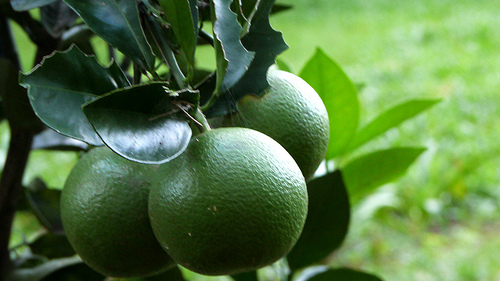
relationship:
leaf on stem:
[78, 79, 194, 167] [165, 52, 204, 132]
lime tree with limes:
[0, 0, 445, 281] [158, 124, 305, 275]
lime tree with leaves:
[0, 0, 445, 281] [118, 99, 175, 147]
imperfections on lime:
[154, 194, 246, 260] [139, 115, 336, 275]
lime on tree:
[141, 121, 312, 278] [3, 4, 380, 279]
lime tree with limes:
[31, 9, 318, 258] [105, 111, 305, 257]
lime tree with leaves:
[31, 9, 318, 258] [70, 32, 185, 128]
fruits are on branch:
[59, 66, 334, 260] [7, 8, 129, 88]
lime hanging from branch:
[141, 121, 312, 278] [160, 40, 217, 130]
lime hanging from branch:
[141, 121, 312, 278] [128, 21, 238, 143]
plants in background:
[371, 0, 499, 246] [251, 48, 495, 178]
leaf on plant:
[78, 79, 194, 167] [3, 2, 446, 279]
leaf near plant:
[78, 47, 192, 121] [138, 46, 403, 226]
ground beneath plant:
[269, 0, 499, 280] [277, 57, 374, 274]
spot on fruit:
[204, 182, 223, 222] [145, 122, 312, 278]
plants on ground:
[269, 0, 498, 280] [269, 0, 499, 280]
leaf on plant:
[19, 46, 114, 148] [3, 2, 446, 279]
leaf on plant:
[280, 166, 360, 278] [0, 2, 359, 279]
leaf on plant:
[341, 146, 428, 208] [273, 45, 443, 280]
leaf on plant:
[288, 41, 365, 170] [3, 2, 446, 279]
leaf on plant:
[282, 165, 352, 272] [3, 2, 446, 279]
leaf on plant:
[201, 0, 259, 112] [3, 2, 446, 279]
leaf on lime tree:
[66, 5, 221, 85] [0, 0, 445, 281]